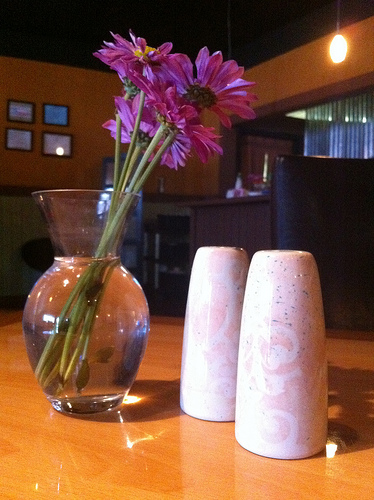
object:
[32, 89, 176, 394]
stem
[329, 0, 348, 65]
light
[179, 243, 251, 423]
shaker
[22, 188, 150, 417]
vase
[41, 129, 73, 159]
frame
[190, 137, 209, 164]
petals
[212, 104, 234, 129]
petals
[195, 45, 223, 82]
petals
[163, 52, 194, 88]
petals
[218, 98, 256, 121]
petals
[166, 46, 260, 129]
flower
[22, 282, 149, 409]
water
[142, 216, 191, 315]
rack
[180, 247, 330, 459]
salt/pepper shakers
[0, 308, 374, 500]
table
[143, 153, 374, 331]
bar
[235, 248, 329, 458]
shaker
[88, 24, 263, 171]
boat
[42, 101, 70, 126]
picture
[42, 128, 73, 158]
picture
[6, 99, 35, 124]
picture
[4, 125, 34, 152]
picture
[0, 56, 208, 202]
wall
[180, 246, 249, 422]
salt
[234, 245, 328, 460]
pepper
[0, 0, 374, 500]
restaurant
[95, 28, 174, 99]
flower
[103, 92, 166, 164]
flower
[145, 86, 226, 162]
flower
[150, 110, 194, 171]
flower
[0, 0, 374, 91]
ceiling